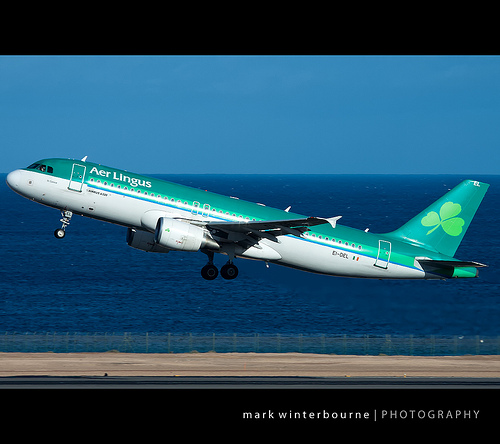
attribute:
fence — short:
[2, 333, 499, 356]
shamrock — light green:
[414, 193, 467, 241]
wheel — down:
[222, 258, 239, 279]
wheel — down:
[198, 252, 219, 280]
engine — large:
[152, 217, 226, 254]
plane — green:
[8, 156, 493, 286]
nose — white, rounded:
[5, 167, 19, 185]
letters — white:
[87, 165, 156, 191]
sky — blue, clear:
[1, 56, 499, 177]